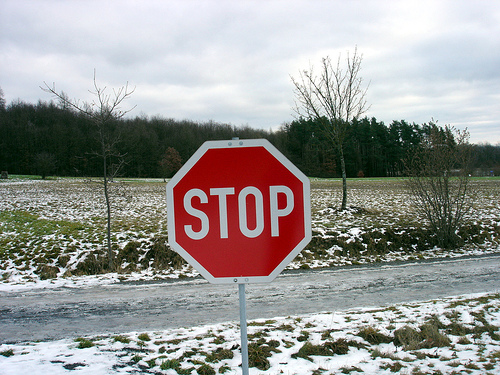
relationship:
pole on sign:
[223, 296, 262, 343] [181, 145, 304, 296]